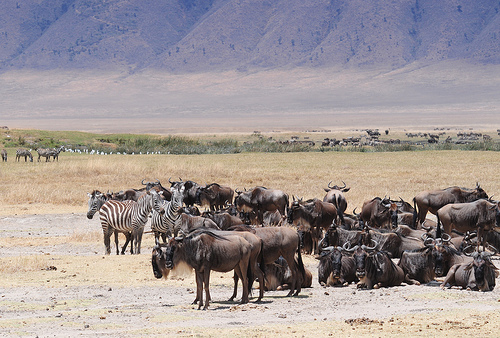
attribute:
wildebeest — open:
[151, 154, 497, 311]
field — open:
[0, 123, 498, 335]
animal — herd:
[148, 230, 259, 311]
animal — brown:
[150, 228, 271, 308]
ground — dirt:
[32, 237, 102, 305]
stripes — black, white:
[136, 203, 161, 221]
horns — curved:
[325, 176, 350, 190]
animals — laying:
[104, 139, 481, 310]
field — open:
[0, 162, 486, 332]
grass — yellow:
[1, 155, 497, 211]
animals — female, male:
[77, 168, 498, 300]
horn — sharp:
[337, 178, 352, 192]